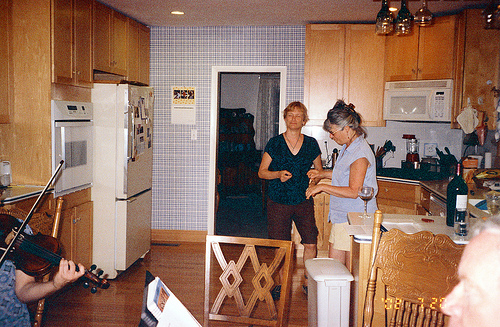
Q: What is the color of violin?
A: Brown.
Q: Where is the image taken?
A: Kitchen.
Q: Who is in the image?
A: Ladies.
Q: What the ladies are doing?
A: Talking.